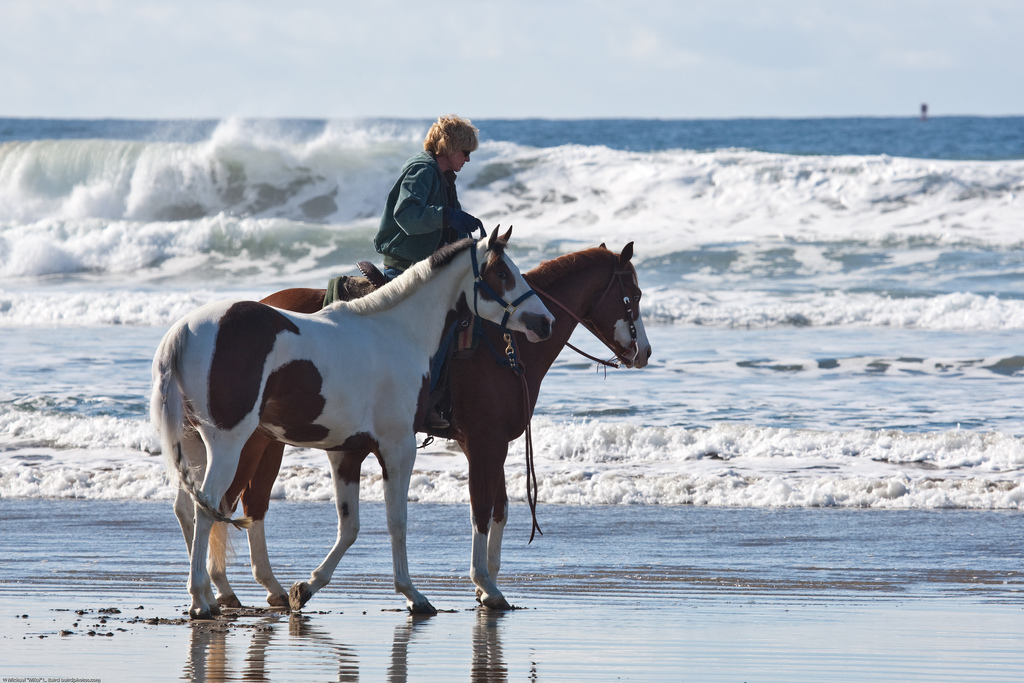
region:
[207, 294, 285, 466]
Large brown spot on the back of horse.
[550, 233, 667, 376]
Head of a brown horse with white spots.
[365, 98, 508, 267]
Woman sitting on top of the horse.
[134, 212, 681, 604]
Two horses walking on the dirt.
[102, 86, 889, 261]
Large tide of water in the ocean.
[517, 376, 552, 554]
Saddle strings hanging from the horse.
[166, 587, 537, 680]
Reflection of horse legs in the sand.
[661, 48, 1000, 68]
Thin white clouds in the snow.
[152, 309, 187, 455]
White hair on the tail of the horse.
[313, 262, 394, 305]
Black saddle under neath the woman sitting on it.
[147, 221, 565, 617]
Horse is white and brown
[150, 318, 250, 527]
White tail of a horse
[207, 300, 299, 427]
Brown spot on a horse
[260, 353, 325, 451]
Brown spot on a horse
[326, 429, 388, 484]
Brown spot on a horse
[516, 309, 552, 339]
Brown spot on a horse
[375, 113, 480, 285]
Woman sitting on a horse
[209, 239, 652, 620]
Woman on a brown horse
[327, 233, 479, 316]
White and brown mane of a horse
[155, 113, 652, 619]
the woman and two horses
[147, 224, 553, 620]
the horse is brown and white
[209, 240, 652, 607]
the horse is predominantly brown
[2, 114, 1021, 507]
the large body of water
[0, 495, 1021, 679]
the sand is wet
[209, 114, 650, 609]
the woman on the horse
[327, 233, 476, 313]
the mane is white and dark brown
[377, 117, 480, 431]
the woman has blond hair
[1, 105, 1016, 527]
White waves in the ocean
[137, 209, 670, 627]
Two horses standing side by side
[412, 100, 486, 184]
A woman has short blonde hair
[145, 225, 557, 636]
The white and brown horse on the beach.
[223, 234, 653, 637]
The horse the person is sitting on.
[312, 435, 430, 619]
The front legs of the white and brown horse.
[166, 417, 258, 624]
The back legs of the white and brown horse.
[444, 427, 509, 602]
The front legs of the dark brown horse.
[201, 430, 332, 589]
The back legs of the dark brown horse.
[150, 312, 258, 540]
The tail of the white and brown horse.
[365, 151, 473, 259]
The jacket the person is wearing.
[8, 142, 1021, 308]
The high waves in the ocean.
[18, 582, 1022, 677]
The sand area where the horses are standing.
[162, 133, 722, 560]
the woman is horseback riding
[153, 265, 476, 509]
there are two horses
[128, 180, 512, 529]
the horse is white and brown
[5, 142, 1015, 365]
the waves are crashing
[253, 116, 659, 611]
Woman is horseback riding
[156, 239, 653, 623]
Two horses walking on the ocean beach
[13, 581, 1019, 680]
Wet sand right by the waves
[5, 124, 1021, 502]
Next swell of waves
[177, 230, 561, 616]
White and brown spotted horse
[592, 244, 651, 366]
Head of brown horse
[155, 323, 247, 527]
Tail on white horse is braided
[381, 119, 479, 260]
Woman is wearing a jean jacket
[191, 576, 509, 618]
Two sets of horse hooves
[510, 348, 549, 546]
Lead rope for horse is dangling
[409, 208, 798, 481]
this horse is brown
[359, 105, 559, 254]
the woman is old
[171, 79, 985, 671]
this is a beach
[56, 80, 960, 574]
these are waves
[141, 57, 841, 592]
the waves are crashing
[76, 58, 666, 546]
the waves are white